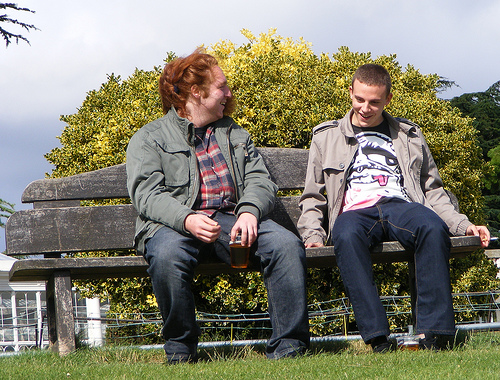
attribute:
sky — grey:
[78, 9, 203, 60]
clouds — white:
[16, 9, 147, 117]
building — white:
[0, 260, 105, 357]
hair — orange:
[155, 49, 205, 119]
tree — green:
[36, 20, 488, 340]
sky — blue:
[389, 17, 496, 55]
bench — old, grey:
[3, 143, 483, 359]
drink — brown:
[230, 239, 252, 269]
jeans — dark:
[331, 196, 462, 341]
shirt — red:
[164, 133, 229, 195]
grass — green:
[156, 350, 498, 375]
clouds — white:
[44, 39, 121, 64]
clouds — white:
[34, 14, 149, 68]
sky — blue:
[4, 2, 494, 165]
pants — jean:
[330, 195, 458, 342]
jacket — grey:
[296, 106, 473, 243]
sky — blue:
[0, 6, 499, 264]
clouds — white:
[2, 3, 498, 263]